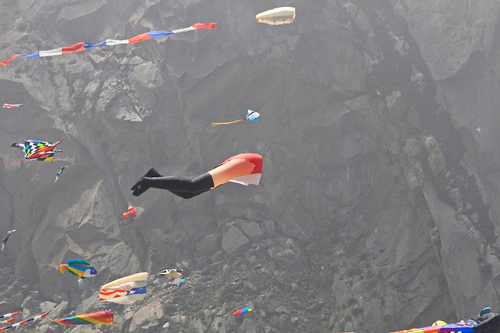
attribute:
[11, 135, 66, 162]
pattern — black, white, checkered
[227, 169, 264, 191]
underside — White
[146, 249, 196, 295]
kite — in the air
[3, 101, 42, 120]
kite — small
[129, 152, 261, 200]
kite — Black, human like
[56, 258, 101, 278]
kite — in the air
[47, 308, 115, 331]
kite — in the air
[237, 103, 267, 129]
kite — in the air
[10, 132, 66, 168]
kite — in the air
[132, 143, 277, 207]
kite — red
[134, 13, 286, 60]
kite — Black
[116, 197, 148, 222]
kite — in the air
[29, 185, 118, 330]
mountain sides — Steep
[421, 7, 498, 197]
mountain sides — Steep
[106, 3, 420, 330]
mountain sides — Steep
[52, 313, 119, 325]
kite — rainbow, colored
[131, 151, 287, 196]
kite — in the air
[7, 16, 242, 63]
long tail — in the air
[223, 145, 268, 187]
clothing — red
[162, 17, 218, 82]
tail — in the air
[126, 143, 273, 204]
kite — in the air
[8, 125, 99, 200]
kite — in the air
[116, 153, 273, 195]
kites — in the air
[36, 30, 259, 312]
kites — in the air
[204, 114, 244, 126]
kite tail — in the air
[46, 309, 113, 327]
kite — in the air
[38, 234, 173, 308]
kite — in the air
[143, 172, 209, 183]
light — reflecting